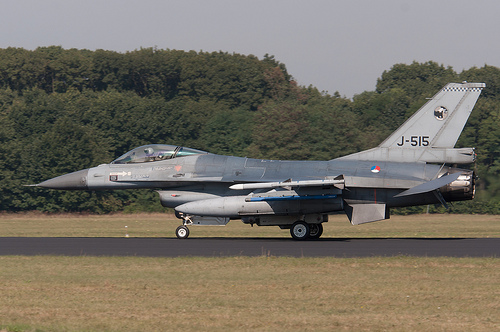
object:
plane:
[18, 83, 488, 243]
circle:
[370, 165, 383, 174]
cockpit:
[110, 144, 207, 165]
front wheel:
[175, 225, 189, 239]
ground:
[0, 207, 500, 332]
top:
[106, 145, 204, 167]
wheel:
[306, 222, 324, 239]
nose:
[20, 168, 88, 191]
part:
[110, 143, 205, 165]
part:
[378, 80, 485, 146]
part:
[439, 168, 476, 198]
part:
[228, 174, 345, 192]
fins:
[393, 171, 463, 198]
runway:
[0, 230, 500, 263]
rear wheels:
[290, 221, 311, 240]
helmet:
[144, 147, 155, 155]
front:
[23, 184, 37, 186]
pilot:
[143, 147, 158, 166]